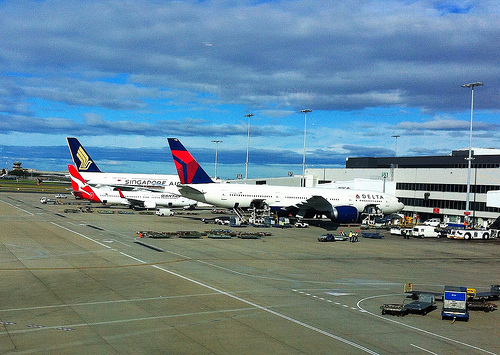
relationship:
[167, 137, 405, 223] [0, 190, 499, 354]
plane on runway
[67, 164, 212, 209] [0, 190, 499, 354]
plane on runway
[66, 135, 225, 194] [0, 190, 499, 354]
plane on runway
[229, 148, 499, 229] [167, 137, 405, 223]
building in front of plane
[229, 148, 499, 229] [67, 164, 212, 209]
building in front of plane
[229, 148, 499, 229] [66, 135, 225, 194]
building in front of plane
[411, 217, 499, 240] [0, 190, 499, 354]
cars on runway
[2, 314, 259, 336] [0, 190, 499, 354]
line on runway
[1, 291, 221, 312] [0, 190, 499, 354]
line on runway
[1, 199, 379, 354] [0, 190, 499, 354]
line on runway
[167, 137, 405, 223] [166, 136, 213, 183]
plane has a tail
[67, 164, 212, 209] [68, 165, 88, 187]
plane has a tail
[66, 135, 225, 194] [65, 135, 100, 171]
plane has a tail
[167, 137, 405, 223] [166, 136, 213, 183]
plane has tail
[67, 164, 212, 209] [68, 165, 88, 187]
plane has tail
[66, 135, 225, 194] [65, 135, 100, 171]
plane has tail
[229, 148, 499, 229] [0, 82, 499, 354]
building in airport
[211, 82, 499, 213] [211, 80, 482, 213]
lights in a line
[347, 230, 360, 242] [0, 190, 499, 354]
people on runway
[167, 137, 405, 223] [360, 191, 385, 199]
plane has a branding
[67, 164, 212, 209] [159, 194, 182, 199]
plane has a branding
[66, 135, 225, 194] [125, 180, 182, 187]
plane has a branding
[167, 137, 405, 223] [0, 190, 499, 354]
plane parked on runway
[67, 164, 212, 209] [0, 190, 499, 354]
plane parked on runway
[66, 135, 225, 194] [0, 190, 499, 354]
plane parked on runway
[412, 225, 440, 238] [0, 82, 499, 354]
van at airport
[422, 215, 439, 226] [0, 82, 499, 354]
van at airport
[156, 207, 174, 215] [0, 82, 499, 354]
van at airport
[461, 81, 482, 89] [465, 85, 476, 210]
light on a pole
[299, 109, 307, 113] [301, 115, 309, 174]
light on a pole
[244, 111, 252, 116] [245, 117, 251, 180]
light on a pole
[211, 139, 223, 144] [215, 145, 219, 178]
light on a pole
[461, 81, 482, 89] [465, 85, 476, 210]
light on pole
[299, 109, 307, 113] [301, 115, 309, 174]
light on pole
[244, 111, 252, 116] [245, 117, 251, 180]
light on pole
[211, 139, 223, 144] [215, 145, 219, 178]
light on pole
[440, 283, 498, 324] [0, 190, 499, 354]
baggage cart on runway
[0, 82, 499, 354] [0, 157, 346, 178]
airport by water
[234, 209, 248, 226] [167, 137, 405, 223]
ramp on plane